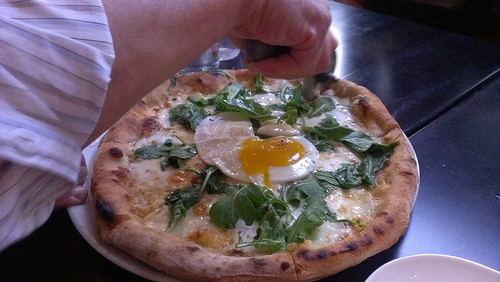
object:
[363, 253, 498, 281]
plate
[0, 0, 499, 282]
table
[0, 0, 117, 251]
shirt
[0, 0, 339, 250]
man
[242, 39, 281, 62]
handle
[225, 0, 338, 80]
hand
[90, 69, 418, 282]
wheel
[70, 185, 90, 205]
finger tip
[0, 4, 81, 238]
pinstripe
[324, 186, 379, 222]
cheese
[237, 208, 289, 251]
leaves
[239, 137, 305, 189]
yolk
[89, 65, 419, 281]
crust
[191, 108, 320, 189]
egg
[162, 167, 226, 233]
spinach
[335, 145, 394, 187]
leaf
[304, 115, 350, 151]
leaf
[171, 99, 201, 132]
leaf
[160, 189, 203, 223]
leaf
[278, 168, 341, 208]
leaf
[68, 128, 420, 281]
plate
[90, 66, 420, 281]
personal pizza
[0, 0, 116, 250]
material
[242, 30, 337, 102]
cutter